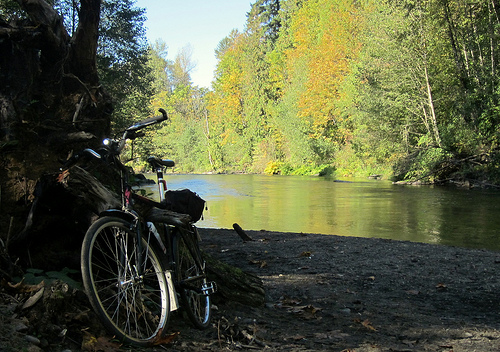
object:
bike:
[43, 104, 221, 350]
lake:
[136, 171, 499, 255]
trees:
[174, 95, 192, 131]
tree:
[348, 0, 447, 152]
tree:
[289, 0, 375, 141]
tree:
[260, 0, 302, 160]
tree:
[209, 27, 249, 170]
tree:
[487, 1, 499, 109]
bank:
[84, 224, 500, 351]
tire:
[169, 228, 212, 330]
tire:
[79, 215, 173, 348]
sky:
[54, 0, 281, 93]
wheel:
[79, 215, 172, 348]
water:
[130, 171, 500, 254]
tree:
[3, 0, 116, 135]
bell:
[102, 137, 113, 147]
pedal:
[200, 280, 218, 296]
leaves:
[333, 60, 341, 67]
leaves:
[230, 91, 238, 97]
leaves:
[234, 44, 243, 54]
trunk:
[56, 162, 123, 213]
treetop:
[213, 28, 244, 59]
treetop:
[169, 51, 195, 76]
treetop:
[144, 43, 167, 64]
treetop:
[195, 82, 217, 104]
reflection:
[161, 177, 274, 201]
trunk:
[61, 0, 103, 86]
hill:
[0, 0, 155, 352]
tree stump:
[231, 222, 252, 241]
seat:
[146, 156, 175, 174]